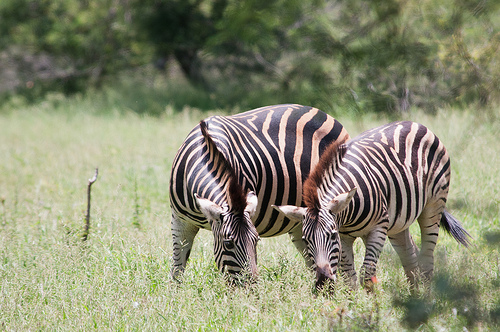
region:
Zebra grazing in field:
[162, 109, 346, 297]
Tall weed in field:
[82, 163, 100, 245]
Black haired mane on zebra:
[196, 121, 247, 219]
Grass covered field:
[5, 99, 499, 330]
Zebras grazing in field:
[163, 97, 470, 305]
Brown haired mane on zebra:
[301, 132, 347, 224]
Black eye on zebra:
[221, 233, 239, 252]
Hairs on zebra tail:
[441, 206, 476, 251]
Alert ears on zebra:
[268, 182, 362, 228]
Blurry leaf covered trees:
[3, 5, 495, 110]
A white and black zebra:
[318, 109, 477, 309]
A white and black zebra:
[155, 109, 305, 259]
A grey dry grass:
[1, 236, 102, 323]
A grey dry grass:
[115, 266, 252, 320]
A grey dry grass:
[265, 255, 340, 327]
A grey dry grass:
[10, 155, 75, 250]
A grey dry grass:
[81, 101, 176, 168]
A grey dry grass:
[454, 109, 489, 201]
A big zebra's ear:
[265, 191, 307, 226]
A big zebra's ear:
[329, 180, 358, 214]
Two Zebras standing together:
[159, 71, 469, 330]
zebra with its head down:
[188, 188, 266, 283]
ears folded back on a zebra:
[186, 185, 273, 224]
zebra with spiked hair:
[283, 130, 350, 240]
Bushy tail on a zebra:
[440, 205, 473, 258]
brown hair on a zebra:
[278, 125, 359, 250]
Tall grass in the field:
[42, 123, 141, 308]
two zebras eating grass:
[204, 186, 362, 318]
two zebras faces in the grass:
[195, 196, 370, 297]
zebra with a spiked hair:
[203, 117, 247, 214]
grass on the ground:
[13, 262, 111, 325]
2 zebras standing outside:
[170, 98, 467, 330]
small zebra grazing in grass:
[272, 122, 470, 305]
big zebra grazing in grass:
[166, 102, 339, 288]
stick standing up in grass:
[83, 169, 108, 258]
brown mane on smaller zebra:
[304, 136, 344, 197]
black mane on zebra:
[211, 120, 255, 225]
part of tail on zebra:
[441, 212, 474, 253]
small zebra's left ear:
[338, 183, 357, 216]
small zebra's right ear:
[275, 202, 309, 228]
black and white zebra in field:
[169, 106, 259, 302]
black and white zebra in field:
[325, 156, 391, 266]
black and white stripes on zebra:
[192, 143, 280, 219]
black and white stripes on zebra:
[295, 168, 391, 228]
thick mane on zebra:
[289, 143, 341, 208]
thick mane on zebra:
[209, 119, 237, 201]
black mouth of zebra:
[304, 276, 320, 293]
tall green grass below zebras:
[27, 227, 110, 319]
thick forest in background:
[77, 16, 379, 108]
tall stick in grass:
[68, 166, 121, 236]